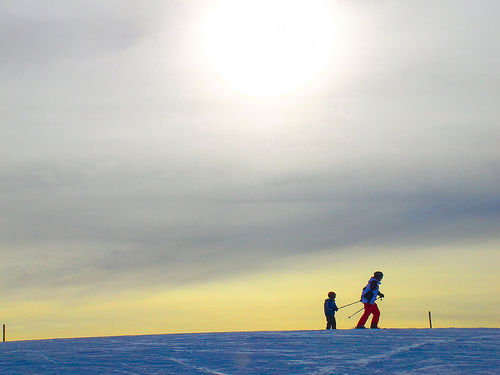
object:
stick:
[428, 311, 433, 328]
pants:
[356, 302, 380, 327]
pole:
[348, 296, 382, 319]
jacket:
[361, 276, 382, 304]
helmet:
[374, 271, 384, 280]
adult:
[355, 271, 384, 329]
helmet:
[328, 292, 337, 300]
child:
[323, 291, 338, 330]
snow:
[2, 327, 500, 374]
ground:
[1, 328, 498, 373]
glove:
[379, 294, 384, 298]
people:
[324, 271, 385, 330]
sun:
[170, 1, 369, 133]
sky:
[0, 1, 499, 342]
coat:
[324, 299, 338, 316]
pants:
[326, 316, 336, 330]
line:
[317, 339, 449, 374]